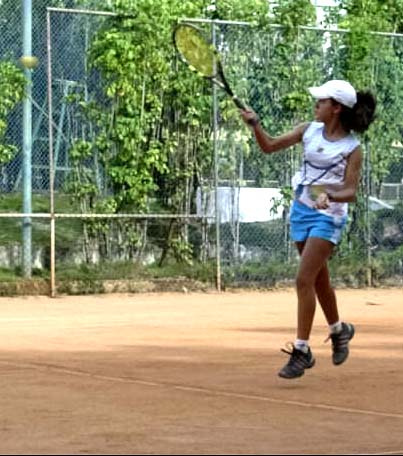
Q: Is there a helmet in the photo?
A: No, there are no helmets.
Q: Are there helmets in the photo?
A: No, there are no helmets.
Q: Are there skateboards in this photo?
A: No, there are no skateboards.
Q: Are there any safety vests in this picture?
A: No, there are no safety vests.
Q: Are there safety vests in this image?
A: No, there are no safety vests.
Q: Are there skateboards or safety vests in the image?
A: No, there are no safety vests or skateboards.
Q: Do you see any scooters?
A: No, there are no scooters.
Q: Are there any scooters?
A: No, there are no scooters.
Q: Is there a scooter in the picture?
A: No, there are no scooters.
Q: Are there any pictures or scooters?
A: No, there are no scooters or pictures.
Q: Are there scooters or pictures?
A: No, there are no scooters or pictures.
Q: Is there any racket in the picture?
A: Yes, there is a racket.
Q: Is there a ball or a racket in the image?
A: Yes, there is a racket.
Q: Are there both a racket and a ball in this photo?
A: Yes, there are both a racket and a ball.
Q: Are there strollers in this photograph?
A: No, there are no strollers.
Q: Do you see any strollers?
A: No, there are no strollers.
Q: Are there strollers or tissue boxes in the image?
A: No, there are no strollers or tissue boxes.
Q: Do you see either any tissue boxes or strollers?
A: No, there are no strollers or tissue boxes.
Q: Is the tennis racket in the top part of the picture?
A: Yes, the tennis racket is in the top of the image.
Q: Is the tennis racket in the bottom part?
A: No, the tennis racket is in the top of the image.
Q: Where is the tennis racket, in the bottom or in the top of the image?
A: The tennis racket is in the top of the image.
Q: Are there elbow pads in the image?
A: No, there are no elbow pads.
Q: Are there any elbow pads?
A: No, there are no elbow pads.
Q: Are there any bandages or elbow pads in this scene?
A: No, there are no elbow pads or bandages.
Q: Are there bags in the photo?
A: No, there are no bags.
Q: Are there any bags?
A: No, there are no bags.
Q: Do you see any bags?
A: No, there are no bags.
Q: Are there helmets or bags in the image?
A: No, there are no bags or helmets.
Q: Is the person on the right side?
A: Yes, the person is on the right of the image.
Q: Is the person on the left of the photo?
A: No, the person is on the right of the image.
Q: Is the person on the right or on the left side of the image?
A: The person is on the right of the image.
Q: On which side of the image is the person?
A: The person is on the right of the image.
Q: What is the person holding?
A: The person is holding the racket.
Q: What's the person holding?
A: The person is holding the racket.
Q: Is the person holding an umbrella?
A: No, the person is holding the tennis racket.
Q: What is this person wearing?
A: The person is wearing a cap.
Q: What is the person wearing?
A: The person is wearing a cap.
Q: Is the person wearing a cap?
A: Yes, the person is wearing a cap.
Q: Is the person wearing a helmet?
A: No, the person is wearing a cap.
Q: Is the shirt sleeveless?
A: Yes, the shirt is sleeveless.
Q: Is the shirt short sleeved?
A: No, the shirt is sleeveless.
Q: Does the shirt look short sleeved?
A: No, the shirt is sleeveless.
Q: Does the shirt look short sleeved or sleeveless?
A: The shirt is sleeveless.